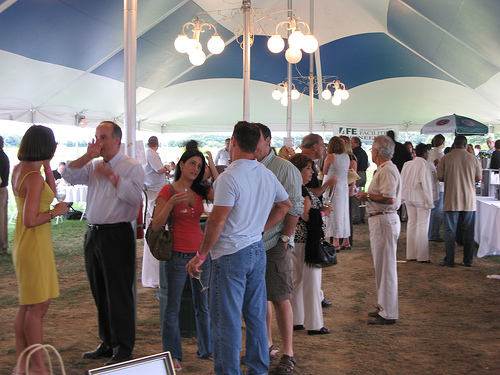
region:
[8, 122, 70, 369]
A woman wearing a yellow dress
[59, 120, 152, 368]
A man wearing a white dress shirt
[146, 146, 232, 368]
A woman wearing a red shirt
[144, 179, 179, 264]
A purse hanging from a woman's shoulder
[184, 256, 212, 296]
A wine glass in a hand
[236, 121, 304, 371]
A man wearing a light green shirt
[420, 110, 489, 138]
A blue and white umbrella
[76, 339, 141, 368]
Black men's dress shoes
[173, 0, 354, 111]
Lights hanging from the ceiling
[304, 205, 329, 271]
A black scarf draped on a woman's arm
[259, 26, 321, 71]
Small light fixtures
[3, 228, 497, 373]
Dirty floors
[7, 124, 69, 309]
Woman wearing yellow sundress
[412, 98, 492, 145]
Green, red, and white umbrella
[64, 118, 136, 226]
Man talking with his hands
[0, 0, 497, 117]
Blue and white tent top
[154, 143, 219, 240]
Woman scratching her head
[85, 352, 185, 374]
Top of laptop screen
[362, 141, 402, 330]
Man with gray hair and khaki pants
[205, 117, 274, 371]
Man wearing blue jeans and white shirt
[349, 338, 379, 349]
dirt on the ground.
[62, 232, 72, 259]
grass on the dirt.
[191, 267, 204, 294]
glass in man's hand.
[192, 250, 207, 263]
bracelet on man's wrist.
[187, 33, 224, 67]
lights above the people.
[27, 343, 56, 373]
handles of a bag.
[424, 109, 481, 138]
umbrella under the tent.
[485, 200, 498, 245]
table cloth on table.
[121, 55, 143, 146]
pole supporting the tent.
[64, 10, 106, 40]
top of the tent.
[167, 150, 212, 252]
Woman with red shirt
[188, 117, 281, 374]
Man holding a drink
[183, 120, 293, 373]
Man wearing pink wristband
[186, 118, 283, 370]
Man wearing blue jeans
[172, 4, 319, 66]
Chandelier hanging in tent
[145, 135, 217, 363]
Woman carrying brown purse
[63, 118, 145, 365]
Man wearing white shirt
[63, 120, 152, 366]
Man wearing black dress pants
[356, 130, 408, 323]
Man wearing a watch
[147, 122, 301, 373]
woman having a conversation with two men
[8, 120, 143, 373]
couple in active motion conversation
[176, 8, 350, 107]
two large visible clusters of lights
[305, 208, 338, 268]
carrying matching pocketbook and scarf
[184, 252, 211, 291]
wearing pink bracelet and holding glass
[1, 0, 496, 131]
large tent over head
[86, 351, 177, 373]
picture frame setting on ground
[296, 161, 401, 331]
wearing formal wear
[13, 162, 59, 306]
wearing yellow dress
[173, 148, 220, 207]
combing fingers through hair